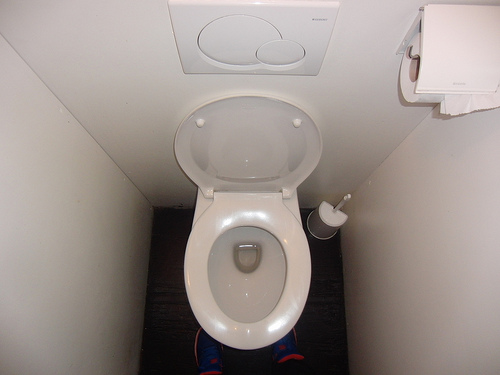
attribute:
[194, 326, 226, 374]
shoe — blue, sneaker, red, black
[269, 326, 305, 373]
shoe — blue, sneaker, red, black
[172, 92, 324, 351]
toilet — white, small, shiny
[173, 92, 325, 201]
lid — up, white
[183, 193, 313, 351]
seat — shiny, white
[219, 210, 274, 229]
reflection — light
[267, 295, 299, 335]
reflection — light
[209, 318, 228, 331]
reflection — light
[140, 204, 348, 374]
floor — wood, brown, black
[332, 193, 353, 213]
toilet brush — white, handle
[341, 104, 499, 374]
wall — white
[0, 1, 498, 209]
wall — white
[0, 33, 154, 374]
wall — white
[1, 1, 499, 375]
scene — indoors, tiny bathroom, bathroom, small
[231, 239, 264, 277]
water — at bottom, low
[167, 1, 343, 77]
panel — white, for flushing, mounted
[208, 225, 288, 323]
bowl — inside, unused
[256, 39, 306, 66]
button — circle, small